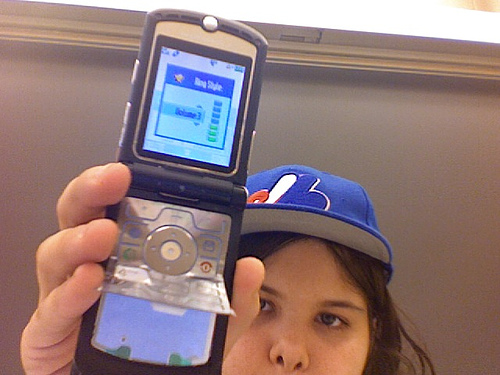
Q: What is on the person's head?
A: A hat.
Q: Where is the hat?
A: On the person's head.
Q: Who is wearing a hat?
A: The person looking at the camera.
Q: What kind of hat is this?
A: A baseball cap.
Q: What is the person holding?
A: A cell phone.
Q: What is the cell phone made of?
A: Plastic and metal.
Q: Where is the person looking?
A: At the camera.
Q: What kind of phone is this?
A: A flip phone.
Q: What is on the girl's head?
A: Baseball cap.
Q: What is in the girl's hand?
A: Cell phone.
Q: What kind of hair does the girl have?
A: Brunette.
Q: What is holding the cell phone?
A: A hand.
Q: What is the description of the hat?
A: Blue, white and red.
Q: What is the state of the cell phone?
A: It is on.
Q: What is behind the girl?
A: A wall.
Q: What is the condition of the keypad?
A: Broken.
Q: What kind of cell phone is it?
A: A flip phone.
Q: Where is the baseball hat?
A: On the girl with the phone.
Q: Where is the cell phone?
A: In the girl's hand.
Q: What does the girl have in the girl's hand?
A: Cell phone.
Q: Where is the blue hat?
A: Lady's head.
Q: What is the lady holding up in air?
A: Phone.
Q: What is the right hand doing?
A: Holding phone.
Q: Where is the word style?
A: On screen of phone.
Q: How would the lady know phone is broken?
A: Keypad bent.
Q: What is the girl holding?
A: A phone.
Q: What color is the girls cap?
A: Blue.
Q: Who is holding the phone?
A: The girl.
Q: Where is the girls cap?
A: On her head.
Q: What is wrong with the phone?
A: Its broken.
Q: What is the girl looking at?
A: The phone.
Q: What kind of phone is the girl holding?
A: Flip phone.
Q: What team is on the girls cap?
A: The Mets.